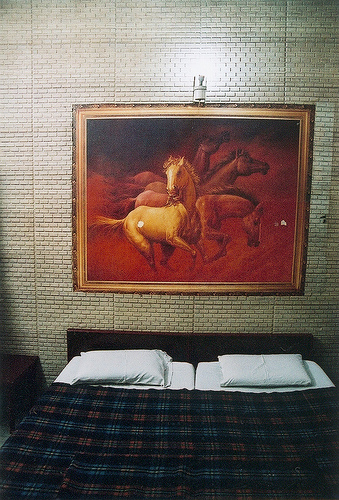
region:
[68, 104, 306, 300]
Framed picture on a wall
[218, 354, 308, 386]
White pillow on a bed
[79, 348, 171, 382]
White pillow on a bed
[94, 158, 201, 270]
Tan horse in a painting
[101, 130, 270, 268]
Horses in a painting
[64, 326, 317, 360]
Brown headboard on bed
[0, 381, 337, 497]
Plaid bedspread on a bed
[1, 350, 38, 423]
Brown table near a bed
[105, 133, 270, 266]
Horses in a painting on the wall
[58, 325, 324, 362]
Brown headboard on bed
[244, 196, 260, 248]
Brown horse's head in painting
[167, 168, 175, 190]
White blaze on horse's face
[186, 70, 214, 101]
Light above painting on a wall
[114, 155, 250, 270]
horses are in picture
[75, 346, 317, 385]
white pillows on bed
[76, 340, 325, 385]
two pillows on bed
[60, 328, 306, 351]
brown and wooden headboard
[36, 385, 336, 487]
blue and brown blanket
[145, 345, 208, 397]
white sheet on bed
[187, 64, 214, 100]
light is above picture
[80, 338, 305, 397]
two white pillowcases on pillows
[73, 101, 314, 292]
a painting hanging on the wall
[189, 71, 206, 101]
light mounted above a painting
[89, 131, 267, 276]
a group of wild horses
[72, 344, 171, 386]
a fluffy white pillow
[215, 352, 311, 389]
a fluffy white pillow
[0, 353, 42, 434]
a small wooden table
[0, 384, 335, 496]
a plaid pattern blanket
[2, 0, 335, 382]
a grey brick wall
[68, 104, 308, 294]
a painting of horses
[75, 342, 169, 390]
Pillow on a bed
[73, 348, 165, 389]
White pillow on a bed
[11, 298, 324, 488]
The bed is made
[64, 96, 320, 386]
Painting above a bed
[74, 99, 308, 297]
Painting is of a horse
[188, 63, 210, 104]
Light on the wall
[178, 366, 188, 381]
Bed sheets are white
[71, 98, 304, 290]
painting of horses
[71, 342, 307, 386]
two pillows on the bed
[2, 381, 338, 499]
plaid blanket on the bed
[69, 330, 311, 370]
black headboard on the bed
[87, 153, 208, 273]
A light brown horse.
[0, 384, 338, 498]
A mostly blue plaid bed cover.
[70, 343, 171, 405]
A pillow on a bed.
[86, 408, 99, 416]
A red square on a blanket.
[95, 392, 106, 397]
A red square on a blanket.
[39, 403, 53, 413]
A red square on a blanket.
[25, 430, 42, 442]
A red square on a blanket.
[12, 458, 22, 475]
A red square on a blanket.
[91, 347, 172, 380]
pillow on the bed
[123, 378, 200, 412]
blanket on the bed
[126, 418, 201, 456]
pattern on the blanket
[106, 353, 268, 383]
pillows on the bed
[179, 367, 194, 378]
sheet on the bed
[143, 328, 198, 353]
headboard of the bed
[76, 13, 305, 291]
painting on the wall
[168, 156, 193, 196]
head of the horse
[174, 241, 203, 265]
leg of the horse